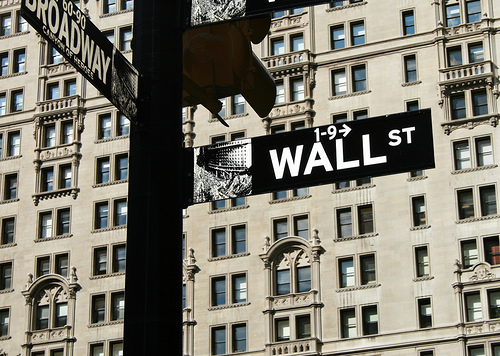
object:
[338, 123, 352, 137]
arrow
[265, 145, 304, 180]
letter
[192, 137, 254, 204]
logo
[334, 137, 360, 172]
letter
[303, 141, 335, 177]
letter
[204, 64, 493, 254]
pole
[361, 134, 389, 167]
letter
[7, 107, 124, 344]
building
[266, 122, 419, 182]
wall street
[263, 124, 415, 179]
letter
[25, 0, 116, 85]
lettering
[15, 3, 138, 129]
street sign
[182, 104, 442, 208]
street sign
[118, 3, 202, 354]
pole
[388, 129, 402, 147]
letter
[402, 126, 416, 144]
letter